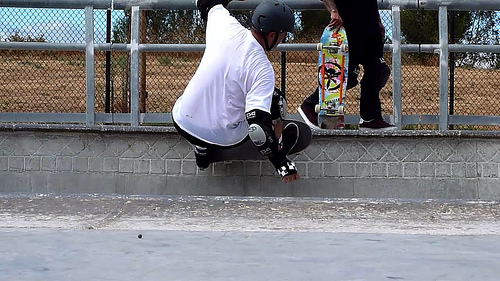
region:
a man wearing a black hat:
[233, 4, 298, 61]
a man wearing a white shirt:
[183, 10, 295, 121]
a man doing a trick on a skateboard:
[148, 7, 324, 177]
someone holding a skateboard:
[309, 6, 375, 141]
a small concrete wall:
[10, 115, 470, 220]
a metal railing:
[1, 5, 177, 115]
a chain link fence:
[24, 27, 172, 104]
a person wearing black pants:
[306, 9, 399, 135]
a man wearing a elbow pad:
[212, 12, 306, 180]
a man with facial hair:
[197, 5, 309, 152]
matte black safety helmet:
[242, 0, 301, 50]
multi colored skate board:
[304, 17, 357, 120]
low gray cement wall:
[4, 134, 496, 208]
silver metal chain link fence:
[5, 6, 498, 122]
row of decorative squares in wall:
[5, 151, 498, 194]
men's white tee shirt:
[170, 1, 285, 176]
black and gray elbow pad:
[237, 100, 283, 158]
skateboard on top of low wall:
[183, 120, 317, 176]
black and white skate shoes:
[352, 112, 404, 139]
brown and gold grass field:
[4, 52, 496, 125]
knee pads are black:
[357, 47, 402, 92]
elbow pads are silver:
[243, 117, 288, 159]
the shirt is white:
[185, 32, 256, 133]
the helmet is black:
[247, 0, 312, 50]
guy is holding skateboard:
[320, 5, 390, 125]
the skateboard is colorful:
[309, 19, 409, 117]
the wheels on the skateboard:
[311, 40, 348, 60]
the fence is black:
[20, 6, 193, 110]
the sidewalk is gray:
[17, 112, 184, 187]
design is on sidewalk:
[339, 140, 489, 177]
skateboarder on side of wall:
[183, 5, 334, 200]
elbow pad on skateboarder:
[241, 117, 266, 157]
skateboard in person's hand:
[309, 19, 355, 128]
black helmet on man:
[254, 1, 296, 36]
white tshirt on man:
[171, 16, 268, 141]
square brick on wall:
[386, 162, 401, 177]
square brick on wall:
[401, 163, 413, 176]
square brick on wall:
[432, 160, 450, 175]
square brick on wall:
[160, 157, 180, 174]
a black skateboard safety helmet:
[250, 0, 296, 46]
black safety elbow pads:
[245, 107, 270, 147]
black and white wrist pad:
[266, 141, 296, 181]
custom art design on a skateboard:
[315, 20, 347, 130]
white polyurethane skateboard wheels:
[313, 102, 320, 114]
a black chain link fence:
[1, 1, 130, 111]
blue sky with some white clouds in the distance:
[0, 7, 85, 42]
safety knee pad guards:
[362, 53, 391, 88]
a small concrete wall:
[323, 138, 498, 201]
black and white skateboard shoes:
[358, 116, 398, 132]